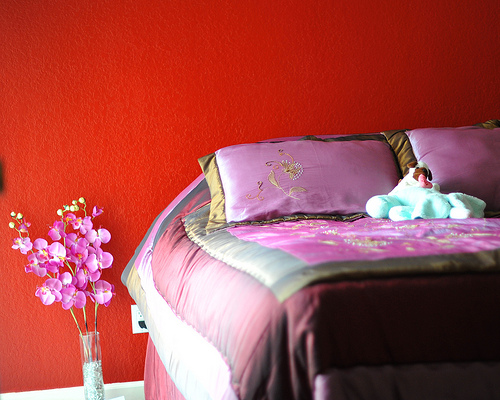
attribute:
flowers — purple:
[5, 197, 145, 337]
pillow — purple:
[219, 126, 424, 247]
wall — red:
[66, 72, 326, 132]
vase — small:
[85, 319, 154, 399]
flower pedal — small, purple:
[34, 286, 49, 298]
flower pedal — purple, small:
[58, 285, 77, 305]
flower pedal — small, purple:
[72, 290, 86, 310]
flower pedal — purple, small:
[58, 270, 75, 287]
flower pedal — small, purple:
[47, 241, 67, 261]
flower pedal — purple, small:
[78, 216, 92, 235]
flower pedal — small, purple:
[96, 251, 113, 269]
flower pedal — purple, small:
[94, 280, 111, 295]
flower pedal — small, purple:
[46, 227, 62, 243]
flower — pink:
[10, 234, 33, 254]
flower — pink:
[33, 276, 63, 304]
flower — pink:
[56, 280, 87, 310]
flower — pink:
[88, 276, 116, 306]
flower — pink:
[80, 247, 113, 272]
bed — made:
[120, 116, 483, 398]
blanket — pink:
[119, 170, 484, 396]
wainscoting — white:
[0, 378, 143, 398]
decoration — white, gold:
[245, 145, 307, 203]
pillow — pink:
[195, 130, 400, 234]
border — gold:
[195, 131, 389, 232]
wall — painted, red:
[1, 1, 484, 391]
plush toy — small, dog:
[395, 157, 441, 191]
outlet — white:
[129, 302, 150, 333]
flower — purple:
[45, 220, 67, 242]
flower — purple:
[69, 212, 93, 235]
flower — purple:
[83, 250, 113, 274]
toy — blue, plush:
[366, 164, 486, 222]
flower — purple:
[59, 282, 89, 311]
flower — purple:
[31, 279, 68, 307]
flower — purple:
[85, 278, 115, 330]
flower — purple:
[69, 248, 98, 286]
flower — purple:
[87, 226, 110, 252]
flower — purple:
[32, 237, 50, 256]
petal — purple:
[98, 226, 110, 244]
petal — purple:
[84, 229, 97, 244]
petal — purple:
[79, 217, 92, 235]